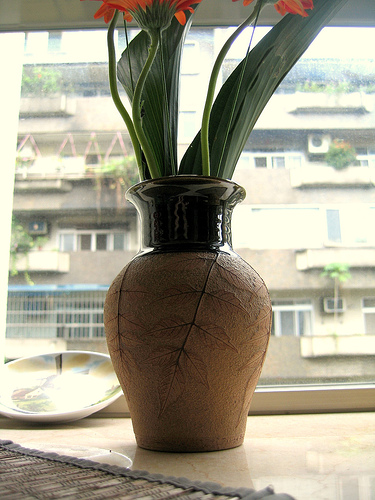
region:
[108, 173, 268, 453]
black and brown vase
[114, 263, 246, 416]
leaf patterns on the vase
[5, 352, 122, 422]
decorative plate leaning against the window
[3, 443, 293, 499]
bamboo mat with brown trim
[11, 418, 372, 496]
light brown marble countertop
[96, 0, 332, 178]
orange flowers with green stems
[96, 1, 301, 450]
orange flowers inside of a decorative vase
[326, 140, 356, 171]
hanging basket with orange flowers on the right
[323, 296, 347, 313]
air conditioning unit on the bottom right apartment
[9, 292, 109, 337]
metal fence on the bottom left of building across the way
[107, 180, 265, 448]
vase sitting on table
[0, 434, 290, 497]
mat sitting on tabletop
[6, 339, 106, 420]
plate leaning against window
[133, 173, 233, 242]
black top of vase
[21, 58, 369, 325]
plants on balconies out the window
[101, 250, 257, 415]
leaf imprints on vase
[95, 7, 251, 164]
stems of flowers in vase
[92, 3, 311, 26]
orange blooms of flower in vase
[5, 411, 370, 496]
table vase and mat are on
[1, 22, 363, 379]
window behind the vase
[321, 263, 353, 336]
a small skinny palm tree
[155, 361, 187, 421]
a leaf on a vase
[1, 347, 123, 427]
a pretty bowl plate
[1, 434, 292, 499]
a grey and beige placemat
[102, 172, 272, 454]
a black and biege vase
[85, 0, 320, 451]
orange flowers in a beige vase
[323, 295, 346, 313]
a window air conditioning unit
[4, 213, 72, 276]
a 2nd story balcony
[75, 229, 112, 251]
double glass porch doors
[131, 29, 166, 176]
the green stem of a flower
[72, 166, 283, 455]
Dark and light brown flower vase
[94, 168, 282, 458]
Textured flower vase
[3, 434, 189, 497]
Placemat on the surface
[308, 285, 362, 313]
Window air conditioner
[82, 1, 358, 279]
Orange flowers in the vase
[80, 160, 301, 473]
Flower vase kept on the shiny white surface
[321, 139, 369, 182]
Plant in the balcony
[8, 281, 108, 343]
Balcony covered with metal grill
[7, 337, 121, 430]
A plate near flower vase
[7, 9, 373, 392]
Open window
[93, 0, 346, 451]
A vase of flowers.